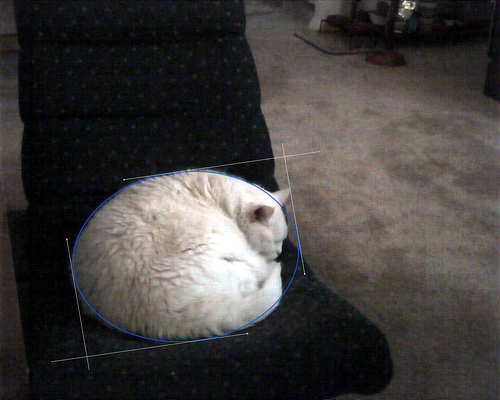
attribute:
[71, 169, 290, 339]
cat — white, sleeping, curled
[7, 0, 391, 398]
chair — office chair, patterned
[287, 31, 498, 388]
carpet — tan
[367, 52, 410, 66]
dish — water dish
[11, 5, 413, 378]
black chair — narrow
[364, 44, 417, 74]
dish — dog food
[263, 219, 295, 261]
face — sleepy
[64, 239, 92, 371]
line — thin, white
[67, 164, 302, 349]
cat — very fuzzy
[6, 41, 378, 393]
chair — padded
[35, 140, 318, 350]
cat — white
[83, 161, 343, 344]
cat —  laying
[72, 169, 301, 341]
circle — blue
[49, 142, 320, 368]
lines — white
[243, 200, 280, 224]
ear — triangular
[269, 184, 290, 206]
ear — triangular